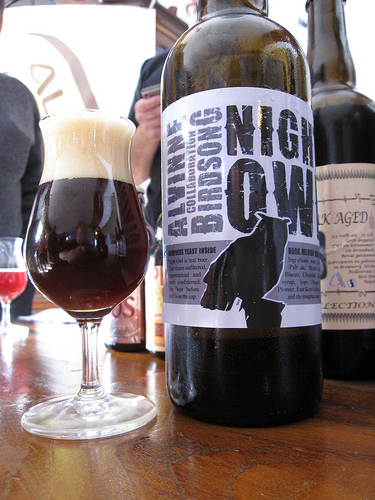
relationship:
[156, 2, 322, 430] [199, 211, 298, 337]
bottle has owl design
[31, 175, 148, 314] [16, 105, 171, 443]
beer in glass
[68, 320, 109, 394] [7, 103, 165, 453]
handle of drink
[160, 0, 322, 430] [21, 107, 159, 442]
bottle of drink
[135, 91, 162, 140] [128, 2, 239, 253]
hand of person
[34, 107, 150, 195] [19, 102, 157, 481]
foam on drink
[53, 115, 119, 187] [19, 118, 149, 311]
head on beer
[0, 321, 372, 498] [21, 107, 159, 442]
table under drink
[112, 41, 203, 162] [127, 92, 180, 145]
cellphone in hand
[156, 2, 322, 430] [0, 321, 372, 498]
bottle on table